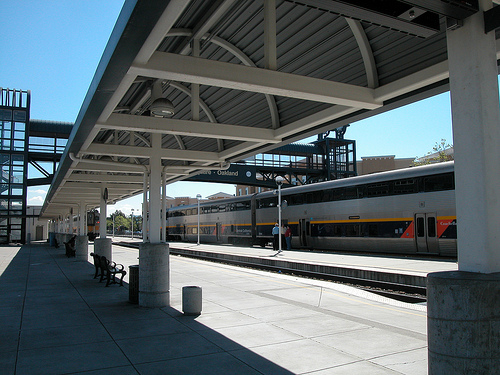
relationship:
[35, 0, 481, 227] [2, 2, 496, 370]
shelter for train station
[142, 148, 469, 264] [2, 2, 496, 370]
train at train station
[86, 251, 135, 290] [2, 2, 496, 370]
bench at train station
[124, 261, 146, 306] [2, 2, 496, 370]
trash can at train station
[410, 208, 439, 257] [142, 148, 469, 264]
doors are on train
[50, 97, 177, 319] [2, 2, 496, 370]
columns are for train station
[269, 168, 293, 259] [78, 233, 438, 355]
lamppost on boarding platform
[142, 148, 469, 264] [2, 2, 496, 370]
train arrived at train station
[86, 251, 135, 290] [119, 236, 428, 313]
bench in front of rails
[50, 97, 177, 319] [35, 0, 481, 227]
columns support shelter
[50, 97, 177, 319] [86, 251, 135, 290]
columns are near bench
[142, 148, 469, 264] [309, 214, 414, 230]
train has line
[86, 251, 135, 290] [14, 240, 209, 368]
bench on sidewalk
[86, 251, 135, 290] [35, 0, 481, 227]
bench under shelter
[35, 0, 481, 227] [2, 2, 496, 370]
shelter covers train station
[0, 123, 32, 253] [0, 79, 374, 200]
stairs lead to walkway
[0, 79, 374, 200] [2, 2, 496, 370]
walkway over train station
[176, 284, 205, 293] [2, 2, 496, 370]
ashtray at train station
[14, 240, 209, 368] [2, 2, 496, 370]
sidewalk at train station